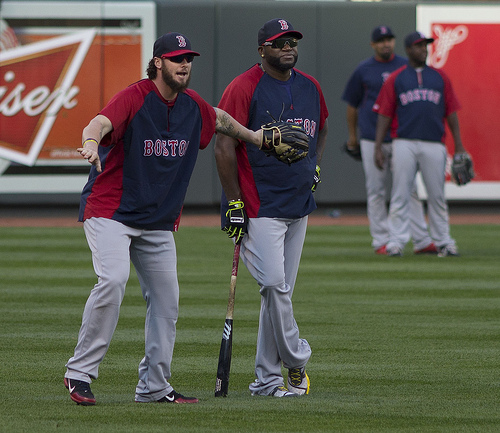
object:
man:
[61, 30, 200, 409]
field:
[1, 209, 499, 432]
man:
[216, 17, 332, 401]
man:
[375, 28, 474, 257]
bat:
[212, 226, 243, 398]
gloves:
[219, 200, 248, 244]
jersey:
[77, 77, 217, 228]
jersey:
[220, 61, 328, 223]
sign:
[0, 1, 155, 191]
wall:
[0, 1, 499, 204]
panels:
[211, 5, 320, 209]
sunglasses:
[168, 55, 195, 63]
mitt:
[259, 123, 310, 166]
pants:
[66, 214, 182, 399]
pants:
[233, 214, 314, 388]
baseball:
[327, 206, 343, 220]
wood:
[225, 277, 236, 319]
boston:
[143, 136, 191, 158]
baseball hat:
[152, 33, 203, 60]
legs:
[235, 224, 310, 366]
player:
[339, 26, 431, 258]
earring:
[261, 53, 265, 58]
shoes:
[61, 369, 98, 406]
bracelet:
[82, 138, 99, 147]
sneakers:
[248, 374, 295, 399]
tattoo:
[216, 114, 234, 137]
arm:
[187, 101, 260, 146]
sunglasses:
[262, 39, 299, 48]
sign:
[417, 3, 500, 201]